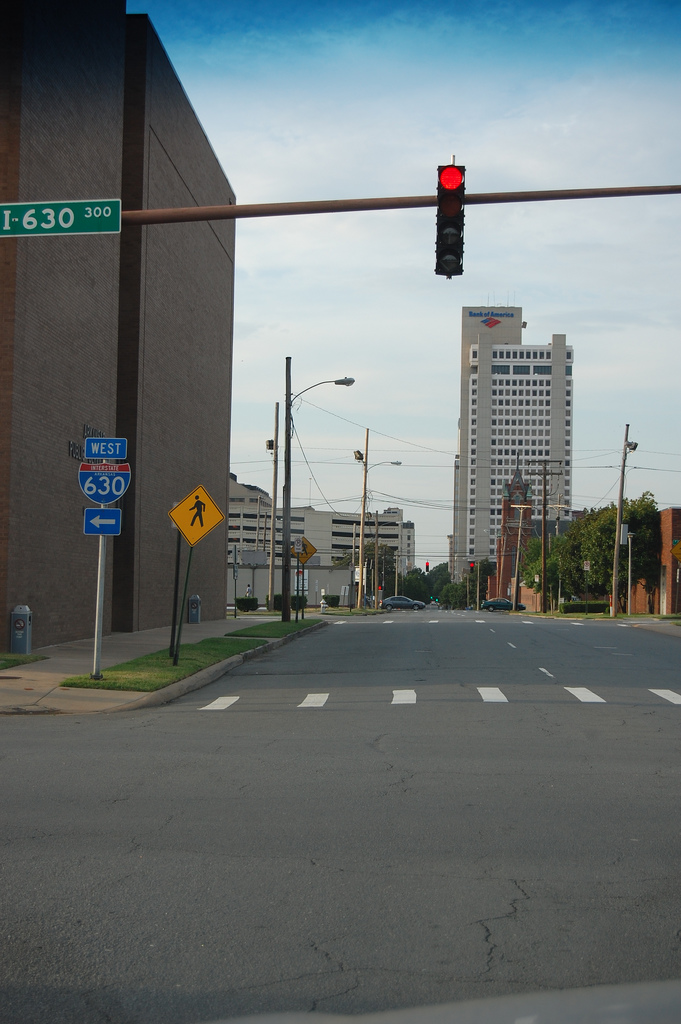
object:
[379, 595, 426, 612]
car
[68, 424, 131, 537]
sign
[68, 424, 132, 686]
post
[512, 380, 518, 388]
window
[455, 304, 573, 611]
building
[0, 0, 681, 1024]
outside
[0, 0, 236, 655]
buildings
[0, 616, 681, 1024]
area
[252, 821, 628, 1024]
cement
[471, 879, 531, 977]
crack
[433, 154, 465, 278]
light